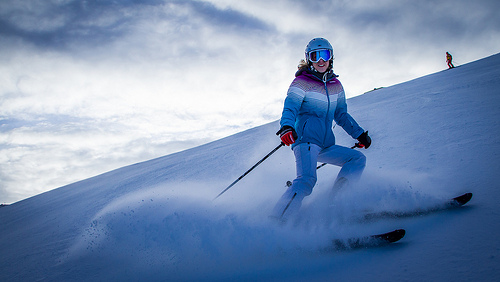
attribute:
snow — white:
[3, 53, 500, 280]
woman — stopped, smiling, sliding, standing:
[258, 30, 376, 230]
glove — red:
[350, 129, 377, 151]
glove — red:
[271, 123, 304, 149]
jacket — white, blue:
[271, 64, 369, 156]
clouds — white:
[1, 1, 500, 205]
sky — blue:
[1, 1, 498, 212]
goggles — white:
[301, 47, 338, 69]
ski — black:
[308, 225, 410, 253]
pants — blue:
[278, 139, 374, 189]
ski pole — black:
[281, 134, 368, 194]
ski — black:
[339, 190, 478, 233]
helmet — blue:
[302, 34, 340, 65]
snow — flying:
[58, 136, 465, 271]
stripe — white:
[284, 84, 344, 109]